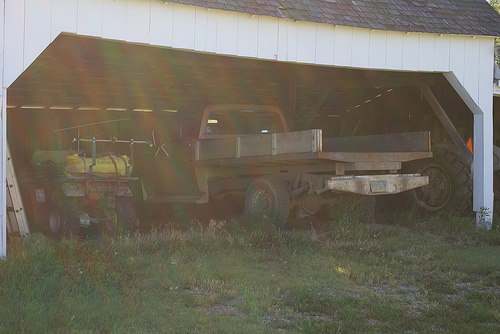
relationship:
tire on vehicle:
[243, 179, 292, 233] [39, 102, 412, 223]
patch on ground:
[330, 262, 353, 279] [4, 210, 498, 332]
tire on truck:
[221, 150, 297, 244] [150, 78, 343, 255]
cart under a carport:
[128, 103, 438, 233] [12, 41, 498, 282]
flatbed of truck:
[195, 127, 435, 173] [139, 96, 497, 239]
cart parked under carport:
[43, 46, 435, 309] [4, 1, 480, 286]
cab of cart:
[118, 91, 283, 220] [128, 103, 438, 233]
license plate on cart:
[371, 179, 389, 192] [128, 103, 438, 233]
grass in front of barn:
[2, 217, 498, 332] [0, 0, 500, 258]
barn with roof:
[0, 0, 500, 258] [145, 1, 497, 40]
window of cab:
[203, 107, 288, 135] [104, 103, 289, 204]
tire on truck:
[243, 179, 292, 233] [123, 86, 461, 241]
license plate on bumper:
[363, 174, 393, 199] [312, 170, 442, 197]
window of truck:
[203, 107, 288, 133] [132, 109, 437, 218]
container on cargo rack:
[61, 146, 141, 177] [35, 157, 157, 244]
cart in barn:
[128, 103, 438, 233] [0, 0, 500, 258]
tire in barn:
[404, 140, 472, 227] [0, 0, 500, 258]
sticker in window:
[206, 116, 230, 131] [204, 107, 330, 134]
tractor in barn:
[20, 135, 147, 234] [0, 0, 500, 258]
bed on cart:
[197, 132, 439, 163] [128, 103, 438, 233]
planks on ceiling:
[46, 7, 477, 77] [197, 72, 372, 142]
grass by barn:
[2, 217, 498, 332] [0, 0, 500, 258]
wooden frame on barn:
[4, 0, 497, 232] [0, 0, 497, 231]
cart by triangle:
[128, 103, 438, 233] [451, 124, 485, 167]